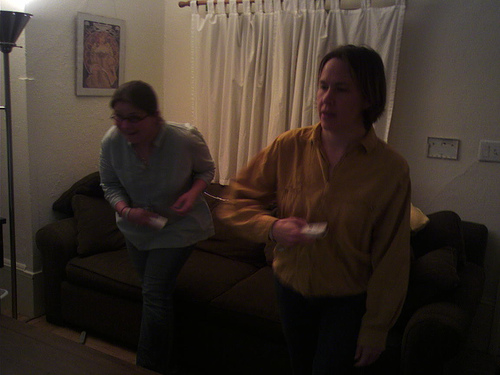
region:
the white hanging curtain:
[190, 0, 404, 185]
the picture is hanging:
[75, 13, 128, 95]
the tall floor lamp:
[0, 8, 33, 328]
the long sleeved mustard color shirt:
[222, 119, 412, 354]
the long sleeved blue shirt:
[100, 122, 216, 252]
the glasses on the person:
[97, 82, 214, 372]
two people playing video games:
[94, 44, 412, 374]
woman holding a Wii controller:
[215, 41, 410, 373]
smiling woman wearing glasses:
[92, 78, 217, 373]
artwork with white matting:
[74, 10, 126, 100]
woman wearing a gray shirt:
[90, 78, 214, 374]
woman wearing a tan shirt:
[215, 42, 409, 374]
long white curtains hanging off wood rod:
[180, 0, 410, 190]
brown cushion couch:
[35, 170, 487, 374]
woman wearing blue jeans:
[94, 78, 217, 373]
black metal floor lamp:
[0, 5, 32, 319]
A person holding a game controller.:
[92, 76, 217, 373]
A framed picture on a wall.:
[69, 6, 129, 103]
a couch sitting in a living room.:
[28, 163, 493, 374]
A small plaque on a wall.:
[422, 130, 464, 165]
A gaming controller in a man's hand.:
[289, 211, 340, 251]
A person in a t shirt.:
[95, 123, 217, 252]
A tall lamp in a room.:
[0, 7, 35, 329]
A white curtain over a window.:
[174, 0, 408, 187]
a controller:
[303, 223, 325, 235]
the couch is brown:
[207, 271, 260, 305]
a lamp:
[1, 8, 26, 51]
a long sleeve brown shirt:
[336, 176, 385, 236]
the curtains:
[188, 19, 311, 103]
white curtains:
[191, 34, 286, 109]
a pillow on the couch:
[419, 248, 451, 288]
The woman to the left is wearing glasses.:
[79, 68, 234, 368]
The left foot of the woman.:
[116, 232, 153, 277]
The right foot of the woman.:
[136, 250, 178, 373]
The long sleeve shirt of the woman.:
[96, 135, 209, 248]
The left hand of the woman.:
[93, 151, 141, 220]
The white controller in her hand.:
[141, 213, 173, 231]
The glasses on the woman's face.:
[104, 112, 159, 124]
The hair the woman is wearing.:
[108, 76, 168, 115]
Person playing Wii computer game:
[92, 87, 209, 356]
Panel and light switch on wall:
[416, 125, 496, 166]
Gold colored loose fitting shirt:
[228, 132, 420, 347]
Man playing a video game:
[240, 35, 440, 363]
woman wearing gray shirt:
[88, 72, 220, 374]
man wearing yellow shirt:
[231, 38, 411, 373]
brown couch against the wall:
[33, 160, 475, 360]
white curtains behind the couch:
[186, 15, 387, 191]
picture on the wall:
[73, 7, 136, 103]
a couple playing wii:
[76, 38, 417, 341]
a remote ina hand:
[258, 201, 348, 258]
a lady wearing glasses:
[74, 43, 249, 271]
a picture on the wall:
[60, 40, 140, 105]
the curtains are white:
[184, 0, 420, 188]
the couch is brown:
[8, 155, 495, 373]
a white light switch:
[472, 131, 498, 169]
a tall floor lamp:
[1, 7, 46, 330]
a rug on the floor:
[6, 323, 125, 373]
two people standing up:
[75, 37, 466, 368]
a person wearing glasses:
[80, 50, 222, 368]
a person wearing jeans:
[67, 70, 239, 370]